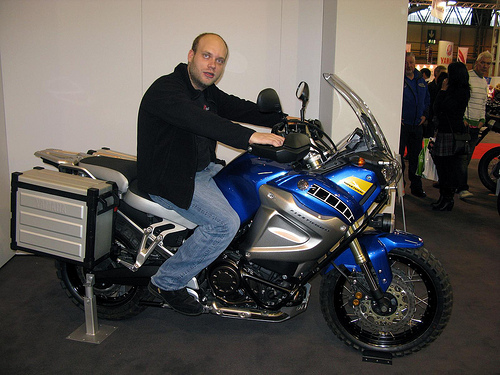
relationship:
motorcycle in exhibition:
[14, 105, 489, 362] [4, 5, 474, 371]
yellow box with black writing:
[341, 176, 374, 198] [342, 179, 365, 193]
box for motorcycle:
[8, 165, 121, 273] [11, 75, 454, 361]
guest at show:
[430, 62, 470, 212] [3, 5, 495, 367]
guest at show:
[459, 48, 491, 203] [3, 5, 495, 367]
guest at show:
[404, 51, 429, 197] [3, 5, 495, 367]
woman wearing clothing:
[435, 59, 470, 194] [438, 86, 468, 195]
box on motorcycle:
[7, 165, 127, 264] [11, 75, 454, 361]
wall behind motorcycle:
[11, 7, 402, 181] [39, 70, 444, 339]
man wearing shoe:
[135, 31, 309, 317] [143, 282, 204, 316]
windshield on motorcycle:
[321, 72, 393, 159] [32, 71, 455, 360]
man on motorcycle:
[135, 31, 309, 317] [11, 75, 454, 361]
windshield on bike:
[323, 70, 393, 162] [52, 76, 448, 351]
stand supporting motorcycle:
[65, 270, 123, 344] [11, 75, 454, 361]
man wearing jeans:
[135, 31, 309, 317] [138, 167, 255, 320]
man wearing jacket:
[137, 31, 306, 317] [133, 62, 288, 213]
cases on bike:
[9, 155, 113, 270] [13, 125, 473, 357]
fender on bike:
[326, 225, 426, 289] [41, 100, 453, 357]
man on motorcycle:
[135, 31, 309, 317] [32, 71, 455, 360]